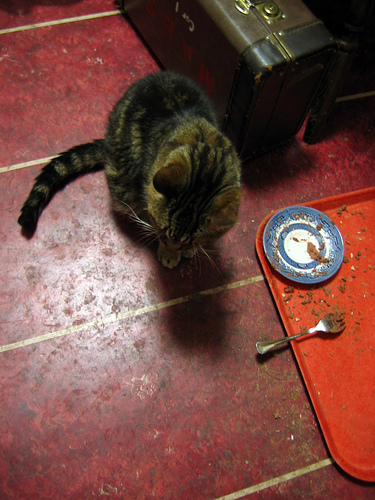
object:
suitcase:
[111, 0, 340, 161]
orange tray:
[254, 186, 372, 483]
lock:
[233, 0, 289, 31]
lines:
[0, 272, 266, 353]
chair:
[302, 0, 375, 140]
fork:
[254, 307, 350, 362]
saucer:
[301, 230, 330, 271]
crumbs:
[320, 282, 362, 312]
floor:
[1, 0, 375, 500]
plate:
[261, 203, 347, 287]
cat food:
[283, 285, 353, 308]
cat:
[16, 65, 246, 272]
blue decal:
[261, 201, 345, 286]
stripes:
[188, 105, 229, 194]